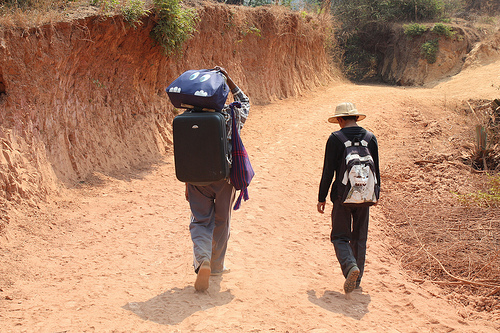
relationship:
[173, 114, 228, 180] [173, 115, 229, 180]
black dark suitcase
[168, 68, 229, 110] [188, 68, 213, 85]
bag with eyes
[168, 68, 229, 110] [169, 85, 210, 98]
bag with hands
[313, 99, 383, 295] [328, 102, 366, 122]
person wearing hat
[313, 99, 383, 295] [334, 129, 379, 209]
person with bag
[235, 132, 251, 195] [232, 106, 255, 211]
red striped bag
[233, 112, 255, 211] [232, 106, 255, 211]
blue shoulder bag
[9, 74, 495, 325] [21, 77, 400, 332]
dirt brown pathway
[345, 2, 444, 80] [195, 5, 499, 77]
plants in distance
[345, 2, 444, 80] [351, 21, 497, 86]
plants on ground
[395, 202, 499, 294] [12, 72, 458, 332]
sticks on ground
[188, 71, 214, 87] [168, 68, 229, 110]
face on luggage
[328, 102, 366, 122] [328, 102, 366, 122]
tan brimmed hat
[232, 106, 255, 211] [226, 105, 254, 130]
bag on shoulder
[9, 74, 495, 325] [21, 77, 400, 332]
clay dirt road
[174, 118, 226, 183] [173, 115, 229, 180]
shell on luggage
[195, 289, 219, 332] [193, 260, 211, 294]
tread of boot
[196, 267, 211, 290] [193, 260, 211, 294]
rubber of shoe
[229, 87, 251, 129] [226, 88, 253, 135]
sleave plaid shirt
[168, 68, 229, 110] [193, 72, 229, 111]
suitcase om head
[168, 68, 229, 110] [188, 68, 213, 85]
suitcase has eyes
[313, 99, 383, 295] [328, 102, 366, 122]
mam has hat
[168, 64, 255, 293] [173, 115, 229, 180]
people has suitcase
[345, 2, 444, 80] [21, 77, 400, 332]
bush off road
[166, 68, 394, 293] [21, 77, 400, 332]
people om path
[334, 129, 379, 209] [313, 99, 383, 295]
backpack worm bi mam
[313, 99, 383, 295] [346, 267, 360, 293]
walker's shoe bottom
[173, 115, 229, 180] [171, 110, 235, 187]
luggage om back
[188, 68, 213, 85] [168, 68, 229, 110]
eyes om luggage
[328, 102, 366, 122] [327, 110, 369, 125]
hat with brim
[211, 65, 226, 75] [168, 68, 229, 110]
hands holdimg luggage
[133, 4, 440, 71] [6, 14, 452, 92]
vegetatiom over ledge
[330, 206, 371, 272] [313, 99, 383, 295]
pamts of walker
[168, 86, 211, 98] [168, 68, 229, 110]
feet om luggage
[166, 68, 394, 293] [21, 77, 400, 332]
mem along road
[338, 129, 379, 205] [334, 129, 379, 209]
black amd white backpack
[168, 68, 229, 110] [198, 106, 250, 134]
bag om shoulders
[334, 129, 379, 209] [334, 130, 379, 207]
pack om back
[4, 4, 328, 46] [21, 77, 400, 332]
cliff along road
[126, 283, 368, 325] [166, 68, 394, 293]
shadows of mem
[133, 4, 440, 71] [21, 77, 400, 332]
weeds beside road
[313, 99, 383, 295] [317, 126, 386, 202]
mam wearing shirt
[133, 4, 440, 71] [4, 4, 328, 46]
bush off ridge